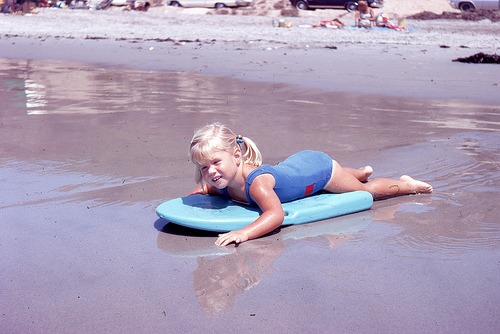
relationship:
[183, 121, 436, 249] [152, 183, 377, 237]
girl on boogie board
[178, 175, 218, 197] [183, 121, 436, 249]
right arm of girl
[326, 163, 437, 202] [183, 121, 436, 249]
left leg of girl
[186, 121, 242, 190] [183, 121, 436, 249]
head of girl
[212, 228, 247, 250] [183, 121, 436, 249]
hand of girl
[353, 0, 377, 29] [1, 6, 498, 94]
person on beach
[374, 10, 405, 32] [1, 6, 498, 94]
person on beach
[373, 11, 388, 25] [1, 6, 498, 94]
ball on beach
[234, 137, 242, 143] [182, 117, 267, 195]
ponytail holder in hair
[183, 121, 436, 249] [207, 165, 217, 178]
girl has nose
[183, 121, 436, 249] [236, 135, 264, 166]
girl has ponytail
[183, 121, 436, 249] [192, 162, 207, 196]
girl has ponytail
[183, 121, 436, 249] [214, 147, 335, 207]
girl in bathing suit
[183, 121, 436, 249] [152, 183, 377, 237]
girl laying on boogie board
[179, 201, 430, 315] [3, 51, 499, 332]
reflection in water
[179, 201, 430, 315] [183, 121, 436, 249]
reflection of girl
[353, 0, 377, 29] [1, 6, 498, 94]
person sitting on beach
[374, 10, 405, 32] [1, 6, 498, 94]
person sitting on beach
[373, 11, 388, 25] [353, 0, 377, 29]
ball next to person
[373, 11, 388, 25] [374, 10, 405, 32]
ball next to person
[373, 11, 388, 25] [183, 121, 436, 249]
ball of girl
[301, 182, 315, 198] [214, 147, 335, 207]
decoration on bathing suit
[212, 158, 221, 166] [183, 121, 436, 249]
eye of girl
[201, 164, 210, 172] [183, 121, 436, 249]
eye of girl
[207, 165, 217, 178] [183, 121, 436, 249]
nose of girl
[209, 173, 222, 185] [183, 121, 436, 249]
mouth of girl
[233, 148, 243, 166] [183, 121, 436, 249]
ear of girl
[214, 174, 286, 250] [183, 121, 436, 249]
left arm of girl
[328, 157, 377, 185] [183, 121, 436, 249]
right leg of girl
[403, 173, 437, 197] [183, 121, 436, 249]
foot of girl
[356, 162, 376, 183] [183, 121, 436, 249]
foot of girl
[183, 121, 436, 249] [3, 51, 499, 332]
girl in water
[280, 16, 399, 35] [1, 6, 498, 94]
blanket on beach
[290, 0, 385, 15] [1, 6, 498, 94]
car parked on beach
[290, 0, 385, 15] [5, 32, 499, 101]
car near sand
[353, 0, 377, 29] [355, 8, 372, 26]
person wearing beach dress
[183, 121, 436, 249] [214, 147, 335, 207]
girl wearing bathing suit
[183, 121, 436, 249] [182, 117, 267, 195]
girl has hair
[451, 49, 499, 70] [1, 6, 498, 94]
sea weed on beach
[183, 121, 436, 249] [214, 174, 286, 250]
girl has left arm